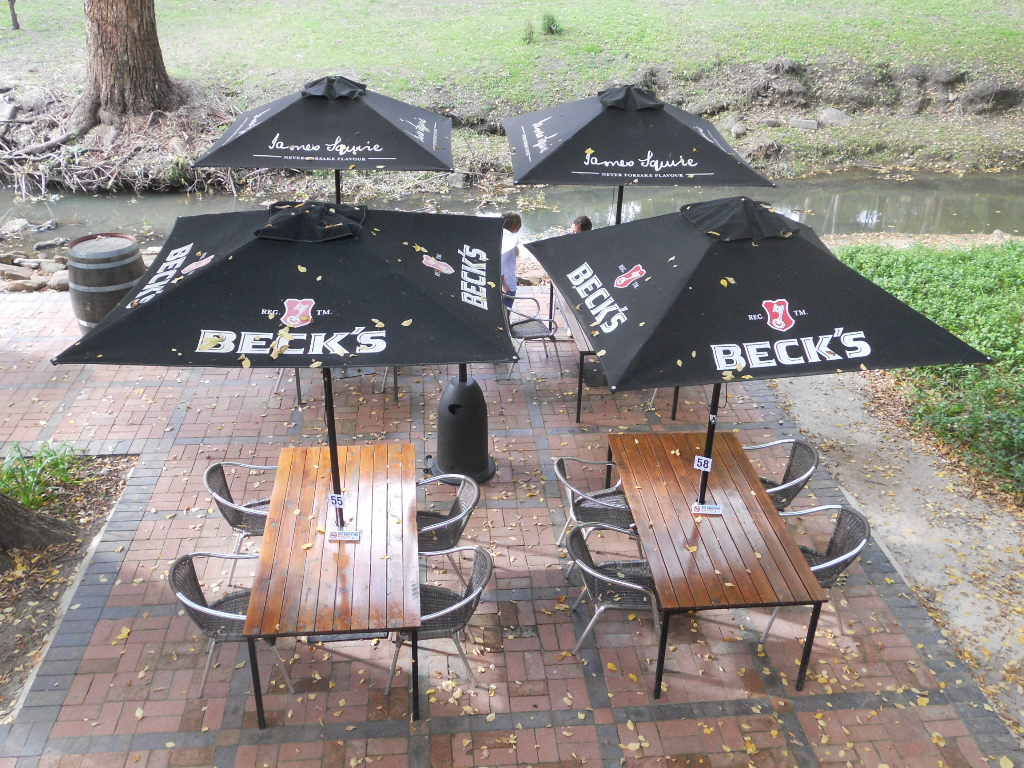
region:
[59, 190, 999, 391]
two black Beck's umbrellas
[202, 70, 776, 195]
two black Squire umbrellas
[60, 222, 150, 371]
a wooden barrel to the side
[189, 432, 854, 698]
two wooden tables with chairs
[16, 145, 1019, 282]
a small creek by the tables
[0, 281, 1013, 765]
red and gray bricks on the ground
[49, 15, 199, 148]
a tree trunk on the other side of the creek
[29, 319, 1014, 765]
many yellow leaves scattered on the ground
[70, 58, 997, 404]
four black umbrellas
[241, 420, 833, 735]
two wooden plank tables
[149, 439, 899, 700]
eight gray and silver chairs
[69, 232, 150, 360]
wooden barrel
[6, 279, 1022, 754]
gray and brown brick patio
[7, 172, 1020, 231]
creek behind the tables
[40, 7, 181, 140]
tree trunk beside the creek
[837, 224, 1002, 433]
grass beside the tables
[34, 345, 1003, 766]
scattered yellow leaves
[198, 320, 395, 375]
The name on the umbrella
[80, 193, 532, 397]
A black umbrella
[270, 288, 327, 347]
the red logo on the umbrella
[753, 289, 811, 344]
A red logo on the umbrella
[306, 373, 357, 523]
The black handle of the umbrella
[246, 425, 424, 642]
The wooden table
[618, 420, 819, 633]
A wooden table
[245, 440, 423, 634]
a brown wooden table top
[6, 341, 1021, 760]
a brick picnic area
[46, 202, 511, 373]
a black umbrella with white letters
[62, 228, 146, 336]
an old fashioned wooden barrel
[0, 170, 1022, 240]
a narrow creek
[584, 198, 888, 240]
light reflecting in the water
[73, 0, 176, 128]
a round brown tree trunk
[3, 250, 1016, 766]
leaves covering the ground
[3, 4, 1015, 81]
flat ground covered with green grass